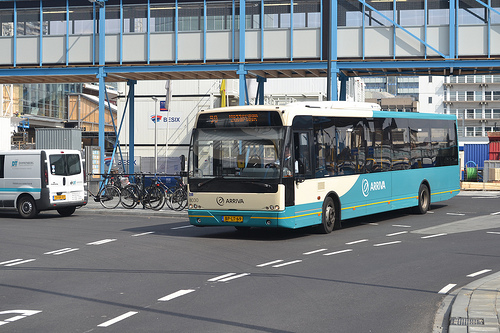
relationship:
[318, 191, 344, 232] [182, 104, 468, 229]
wheel on bus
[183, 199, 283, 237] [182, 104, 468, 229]
headlights are on bus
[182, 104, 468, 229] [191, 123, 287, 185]
bus has a windshield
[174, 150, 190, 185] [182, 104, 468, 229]
mirror on bus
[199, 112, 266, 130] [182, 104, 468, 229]
digital display on bus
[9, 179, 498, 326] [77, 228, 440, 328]
road has stripes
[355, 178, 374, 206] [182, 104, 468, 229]
logo on bus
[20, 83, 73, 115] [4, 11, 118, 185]
window on building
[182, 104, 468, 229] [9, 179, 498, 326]
bus on road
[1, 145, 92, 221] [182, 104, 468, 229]
truck by bus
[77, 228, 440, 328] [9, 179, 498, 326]
stripes are on road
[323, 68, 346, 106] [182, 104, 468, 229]
pole over bus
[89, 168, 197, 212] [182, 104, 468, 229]
bikes next to bus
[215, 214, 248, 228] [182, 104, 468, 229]
license plate on bus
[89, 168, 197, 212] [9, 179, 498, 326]
bikes are on road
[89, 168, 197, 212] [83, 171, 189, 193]
bikes are in rack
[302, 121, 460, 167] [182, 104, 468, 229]
window on bus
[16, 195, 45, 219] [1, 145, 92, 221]
wheel on truck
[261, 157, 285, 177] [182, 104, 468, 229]
steering wheel in bus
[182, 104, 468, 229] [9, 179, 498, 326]
bus in road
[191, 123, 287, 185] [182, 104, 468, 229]
windshield on bus